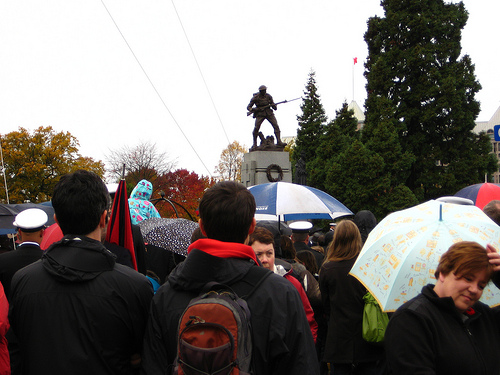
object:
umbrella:
[240, 181, 356, 227]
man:
[147, 181, 323, 374]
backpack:
[172, 260, 276, 374]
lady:
[382, 239, 498, 373]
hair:
[435, 240, 496, 284]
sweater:
[279, 266, 320, 348]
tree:
[291, 65, 328, 191]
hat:
[12, 206, 51, 233]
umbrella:
[136, 214, 199, 259]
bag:
[360, 287, 392, 344]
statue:
[245, 83, 305, 151]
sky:
[0, 0, 499, 194]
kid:
[127, 178, 163, 227]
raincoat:
[128, 177, 162, 227]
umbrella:
[104, 157, 140, 275]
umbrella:
[448, 171, 500, 209]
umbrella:
[349, 197, 498, 319]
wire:
[95, 1, 212, 175]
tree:
[152, 168, 223, 222]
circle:
[264, 162, 285, 185]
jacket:
[144, 236, 327, 375]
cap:
[287, 218, 315, 235]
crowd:
[0, 168, 499, 373]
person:
[327, 219, 338, 239]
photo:
[0, 0, 499, 375]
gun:
[246, 94, 306, 119]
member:
[287, 218, 323, 270]